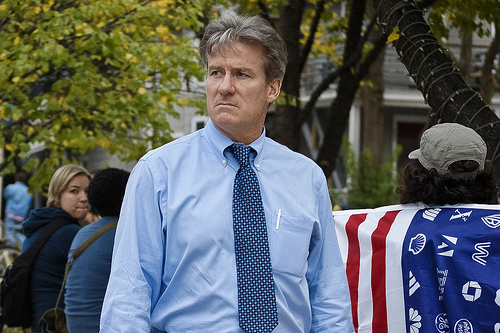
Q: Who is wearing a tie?
A: A man.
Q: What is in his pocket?
A: A pen.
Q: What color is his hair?
A: Salt and pepper.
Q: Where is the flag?
A: To the right of the man.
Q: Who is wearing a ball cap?
A: The man behind the flag.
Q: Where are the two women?
A: Behind the man.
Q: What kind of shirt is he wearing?
A: A button down shirt.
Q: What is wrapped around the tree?
A: Lights.